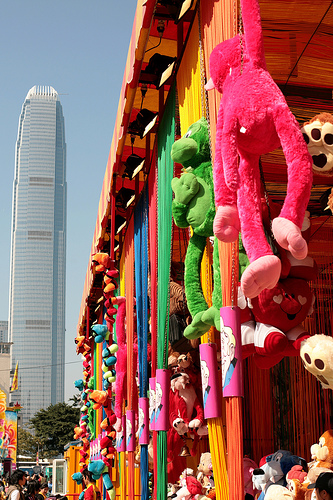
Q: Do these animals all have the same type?
A: No, there are both monkeys and snakes.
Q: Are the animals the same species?
A: No, there are both monkeys and snakes.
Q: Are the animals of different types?
A: Yes, they are monkeys and snakes.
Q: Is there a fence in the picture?
A: No, there are no fences.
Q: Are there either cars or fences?
A: No, there are no fences or cars.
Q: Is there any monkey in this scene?
A: Yes, there is a monkey.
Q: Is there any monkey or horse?
A: Yes, there is a monkey.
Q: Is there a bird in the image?
A: No, there are no birds.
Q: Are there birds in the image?
A: No, there are no birds.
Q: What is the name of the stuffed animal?
A: The animal is a monkey.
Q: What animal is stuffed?
A: The animal is a monkey.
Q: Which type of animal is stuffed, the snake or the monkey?
A: The monkey is stuffed.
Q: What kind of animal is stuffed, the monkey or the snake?
A: The monkey is stuffed.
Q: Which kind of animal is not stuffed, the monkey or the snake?
A: The snake is not stuffed.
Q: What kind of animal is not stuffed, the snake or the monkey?
A: The snake is not stuffed.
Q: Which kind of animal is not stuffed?
A: The animal is a snake.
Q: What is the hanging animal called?
A: The animal is a monkey.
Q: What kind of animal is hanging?
A: The animal is a monkey.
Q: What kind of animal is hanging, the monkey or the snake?
A: The monkey is hanging.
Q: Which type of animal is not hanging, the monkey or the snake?
A: The snake is not hanging.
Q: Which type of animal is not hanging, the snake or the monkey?
A: The snake is not hanging.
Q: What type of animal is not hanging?
A: The animal is a snake.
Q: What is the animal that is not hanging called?
A: The animal is a snake.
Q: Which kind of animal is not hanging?
A: The animal is a snake.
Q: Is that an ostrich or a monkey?
A: That is a monkey.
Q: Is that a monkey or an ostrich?
A: That is a monkey.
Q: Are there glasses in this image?
A: No, there are no glasses.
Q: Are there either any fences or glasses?
A: No, there are no glasses or fences.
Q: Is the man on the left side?
A: Yes, the man is on the left of the image.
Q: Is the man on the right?
A: No, the man is on the left of the image.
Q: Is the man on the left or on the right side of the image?
A: The man is on the left of the image.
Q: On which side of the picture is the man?
A: The man is on the left of the image.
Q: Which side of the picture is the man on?
A: The man is on the left of the image.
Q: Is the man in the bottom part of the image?
A: Yes, the man is in the bottom of the image.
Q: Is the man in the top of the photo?
A: No, the man is in the bottom of the image.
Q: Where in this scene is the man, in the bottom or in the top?
A: The man is in the bottom of the image.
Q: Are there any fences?
A: No, there are no fences.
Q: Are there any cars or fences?
A: No, there are no fences or cars.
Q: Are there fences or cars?
A: No, there are no fences or cars.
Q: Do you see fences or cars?
A: No, there are no fences or cars.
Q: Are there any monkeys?
A: Yes, there is a monkey.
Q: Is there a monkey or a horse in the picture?
A: Yes, there is a monkey.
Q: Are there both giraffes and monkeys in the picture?
A: No, there is a monkey but no giraffes.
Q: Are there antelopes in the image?
A: No, there are no antelopes.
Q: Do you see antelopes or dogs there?
A: No, there are no antelopes or dogs.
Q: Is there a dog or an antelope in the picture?
A: No, there are no antelopes or dogs.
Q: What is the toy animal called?
A: The animal is a monkey.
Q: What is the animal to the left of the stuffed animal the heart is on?
A: The animal is a monkey.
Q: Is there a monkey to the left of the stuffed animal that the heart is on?
A: Yes, there is a monkey to the left of the stuffed animal.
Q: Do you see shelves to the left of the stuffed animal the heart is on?
A: No, there is a monkey to the left of the stuffed animal.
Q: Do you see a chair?
A: No, there are no chairs.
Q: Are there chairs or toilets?
A: No, there are no chairs or toilets.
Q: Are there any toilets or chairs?
A: No, there are no chairs or toilets.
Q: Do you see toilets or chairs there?
A: No, there are no chairs or toilets.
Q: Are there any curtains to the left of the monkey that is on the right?
A: Yes, there is a curtain to the left of the monkey.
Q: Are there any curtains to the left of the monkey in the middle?
A: Yes, there is a curtain to the left of the monkey.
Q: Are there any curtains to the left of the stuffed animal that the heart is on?
A: Yes, there is a curtain to the left of the stuffed animal.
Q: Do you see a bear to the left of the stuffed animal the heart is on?
A: No, there is a curtain to the left of the stuffed animal.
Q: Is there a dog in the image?
A: No, there are no dogs.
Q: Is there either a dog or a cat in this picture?
A: No, there are no dogs or cats.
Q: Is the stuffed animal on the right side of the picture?
A: Yes, the stuffed animal is on the right of the image.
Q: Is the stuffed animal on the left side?
A: No, the stuffed animal is on the right of the image.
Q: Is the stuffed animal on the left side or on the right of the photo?
A: The stuffed animal is on the right of the image.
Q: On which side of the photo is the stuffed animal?
A: The stuffed animal is on the right of the image.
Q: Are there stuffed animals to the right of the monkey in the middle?
A: Yes, there is a stuffed animal to the right of the monkey.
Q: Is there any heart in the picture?
A: Yes, there is a heart.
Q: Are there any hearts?
A: Yes, there is a heart.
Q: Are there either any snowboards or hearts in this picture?
A: Yes, there is a heart.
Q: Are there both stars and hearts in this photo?
A: No, there is a heart but no stars.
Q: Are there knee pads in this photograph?
A: No, there are no knee pads.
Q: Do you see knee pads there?
A: No, there are no knee pads.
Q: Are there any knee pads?
A: No, there are no knee pads.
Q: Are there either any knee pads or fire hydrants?
A: No, there are no knee pads or fire hydrants.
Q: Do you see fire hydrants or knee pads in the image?
A: No, there are no knee pads or fire hydrants.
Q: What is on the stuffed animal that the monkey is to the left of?
A: The heart is on the stuffed animal.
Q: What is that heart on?
A: The heart is on the stuffed animal.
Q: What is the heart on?
A: The heart is on the stuffed animal.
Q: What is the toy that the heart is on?
A: The toy is a stuffed animal.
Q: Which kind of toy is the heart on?
A: The heart is on the stuffed animal.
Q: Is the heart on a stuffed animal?
A: Yes, the heart is on a stuffed animal.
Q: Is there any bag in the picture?
A: No, there are no bags.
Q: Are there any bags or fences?
A: No, there are no bags or fences.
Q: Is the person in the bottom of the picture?
A: Yes, the person is in the bottom of the image.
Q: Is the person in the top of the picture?
A: No, the person is in the bottom of the image.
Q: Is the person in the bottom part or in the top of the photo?
A: The person is in the bottom of the image.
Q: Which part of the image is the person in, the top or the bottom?
A: The person is in the bottom of the image.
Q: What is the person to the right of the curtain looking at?
A: The person is looking at the stuffed animals.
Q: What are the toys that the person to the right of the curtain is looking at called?
A: The toys are stuffed animals.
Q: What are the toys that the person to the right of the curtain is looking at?
A: The toys are stuffed animals.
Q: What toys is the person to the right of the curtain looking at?
A: The person is looking at the stuffed animals.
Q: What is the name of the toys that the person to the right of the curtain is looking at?
A: The toys are stuffed animals.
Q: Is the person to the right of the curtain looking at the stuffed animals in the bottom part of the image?
A: Yes, the person is looking at the stuffed animals.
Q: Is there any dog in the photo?
A: No, there are no dogs.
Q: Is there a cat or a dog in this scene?
A: No, there are no dogs or cats.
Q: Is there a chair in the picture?
A: No, there are no chairs.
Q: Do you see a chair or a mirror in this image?
A: No, there are no chairs or mirrors.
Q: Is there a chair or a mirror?
A: No, there are no chairs or mirrors.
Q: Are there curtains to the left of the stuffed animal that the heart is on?
A: Yes, there is a curtain to the left of the stuffed animal.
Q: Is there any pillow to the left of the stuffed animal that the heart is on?
A: No, there is a curtain to the left of the stuffed animal.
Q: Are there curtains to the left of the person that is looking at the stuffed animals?
A: Yes, there is a curtain to the left of the person.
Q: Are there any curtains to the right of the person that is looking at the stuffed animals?
A: No, the curtain is to the left of the person.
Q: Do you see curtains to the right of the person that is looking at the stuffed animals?
A: No, the curtain is to the left of the person.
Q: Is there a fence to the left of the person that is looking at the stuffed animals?
A: No, there is a curtain to the left of the person.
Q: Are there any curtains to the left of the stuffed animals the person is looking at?
A: Yes, there is a curtain to the left of the stuffed animals.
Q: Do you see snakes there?
A: Yes, there is a snake.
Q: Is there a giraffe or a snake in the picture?
A: Yes, there is a snake.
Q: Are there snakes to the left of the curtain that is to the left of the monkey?
A: Yes, there is a snake to the left of the curtain.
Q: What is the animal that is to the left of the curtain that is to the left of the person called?
A: The animal is a snake.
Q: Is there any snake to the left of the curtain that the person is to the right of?
A: Yes, there is a snake to the left of the curtain.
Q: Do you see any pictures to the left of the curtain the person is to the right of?
A: No, there is a snake to the left of the curtain.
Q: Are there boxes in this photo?
A: No, there are no boxes.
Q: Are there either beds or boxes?
A: No, there are no boxes or beds.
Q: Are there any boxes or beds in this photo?
A: No, there are no boxes or beds.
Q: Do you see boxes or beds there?
A: No, there are no boxes or beds.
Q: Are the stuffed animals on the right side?
A: Yes, the stuffed animals are on the right of the image.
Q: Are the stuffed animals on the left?
A: No, the stuffed animals are on the right of the image.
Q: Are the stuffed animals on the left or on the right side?
A: The stuffed animals are on the right of the image.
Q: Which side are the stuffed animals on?
A: The stuffed animals are on the right of the image.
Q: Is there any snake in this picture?
A: Yes, there is a snake.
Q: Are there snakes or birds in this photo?
A: Yes, there is a snake.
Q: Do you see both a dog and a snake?
A: No, there is a snake but no dogs.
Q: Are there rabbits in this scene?
A: No, there are no rabbits.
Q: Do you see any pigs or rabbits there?
A: No, there are no rabbits or pigs.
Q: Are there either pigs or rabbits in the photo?
A: No, there are no rabbits or pigs.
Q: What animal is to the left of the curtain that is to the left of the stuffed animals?
A: The animal is a snake.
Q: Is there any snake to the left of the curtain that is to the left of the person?
A: Yes, there is a snake to the left of the curtain.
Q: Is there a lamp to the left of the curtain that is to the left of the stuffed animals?
A: No, there is a snake to the left of the curtain.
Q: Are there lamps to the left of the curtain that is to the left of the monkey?
A: No, there is a snake to the left of the curtain.